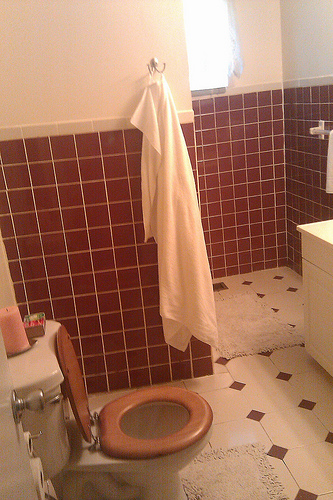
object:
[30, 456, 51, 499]
toilet paper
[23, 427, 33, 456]
toilet paper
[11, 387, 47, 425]
doorknob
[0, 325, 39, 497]
door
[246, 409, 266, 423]
diamond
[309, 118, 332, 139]
towelrack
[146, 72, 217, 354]
white towel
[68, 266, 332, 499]
tile floor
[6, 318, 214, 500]
toilet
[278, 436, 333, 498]
tiles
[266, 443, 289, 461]
pattern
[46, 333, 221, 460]
seat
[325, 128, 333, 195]
towel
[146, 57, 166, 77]
hook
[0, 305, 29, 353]
candle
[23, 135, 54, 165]
tile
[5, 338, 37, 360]
candle holder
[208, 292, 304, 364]
rug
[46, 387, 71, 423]
toilet handle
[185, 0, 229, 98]
window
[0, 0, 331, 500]
bathroom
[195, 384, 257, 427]
tile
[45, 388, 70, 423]
flushing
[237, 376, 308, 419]
tiles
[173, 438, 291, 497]
rug